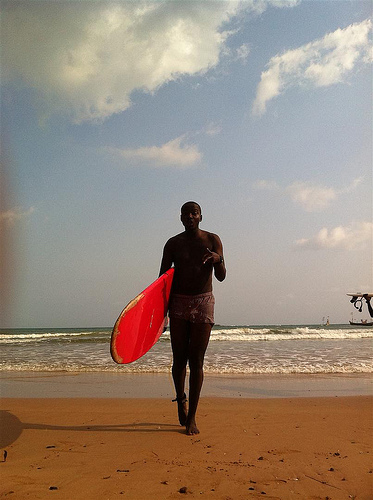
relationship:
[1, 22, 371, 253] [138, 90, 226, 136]
cloud in sky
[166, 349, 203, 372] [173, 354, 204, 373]
knees on a knees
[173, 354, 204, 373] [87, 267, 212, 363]
knees with a surfboard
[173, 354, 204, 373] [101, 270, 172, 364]
knees with a surfboard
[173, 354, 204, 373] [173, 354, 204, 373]
knees of a knees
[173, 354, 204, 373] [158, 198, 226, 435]
knees of a man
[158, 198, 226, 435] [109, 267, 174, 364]
man with a surf board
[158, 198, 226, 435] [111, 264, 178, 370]
man with a surf board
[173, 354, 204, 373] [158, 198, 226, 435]
knees on a man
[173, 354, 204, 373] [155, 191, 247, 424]
knees are on person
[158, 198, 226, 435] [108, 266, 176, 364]
man holding surfboard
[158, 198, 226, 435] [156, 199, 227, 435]
man has dark skin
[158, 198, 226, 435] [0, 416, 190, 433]
man has shadow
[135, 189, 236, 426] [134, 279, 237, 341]
man wearing shorts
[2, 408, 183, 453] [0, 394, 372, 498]
shadow on sand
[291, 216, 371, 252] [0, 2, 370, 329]
cloud in sky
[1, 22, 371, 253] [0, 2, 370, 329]
cloud in sky